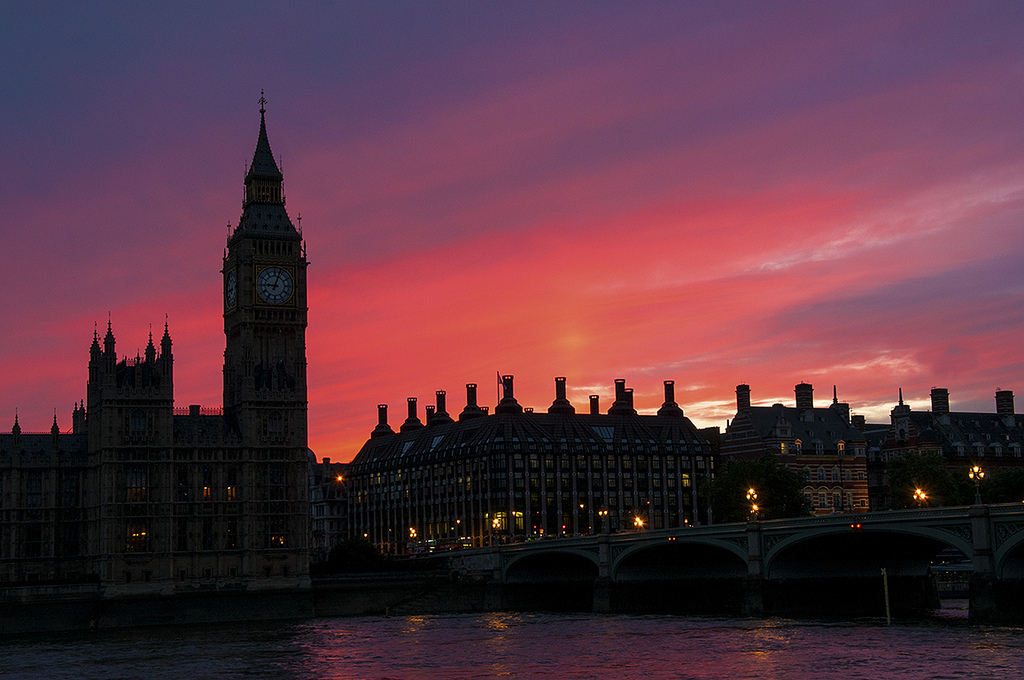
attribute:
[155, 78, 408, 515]
tower — tall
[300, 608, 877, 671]
river — reflecting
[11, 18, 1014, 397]
sky — at dusk, orange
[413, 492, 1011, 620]
bridge — concrete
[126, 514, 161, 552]
light — dim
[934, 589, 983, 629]
sign — small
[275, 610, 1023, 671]
water — blue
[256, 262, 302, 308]
time — 9:05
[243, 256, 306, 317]
clock — white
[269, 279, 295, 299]
hands — black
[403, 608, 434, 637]
light reflection — orange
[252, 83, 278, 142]
top — pointed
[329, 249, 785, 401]
cloud area — orange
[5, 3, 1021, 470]
sky — multicolored, purple, pink, blue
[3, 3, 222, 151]
cloud area — purplish-blue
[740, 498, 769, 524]
street light — gold-colored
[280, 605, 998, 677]
water — blue